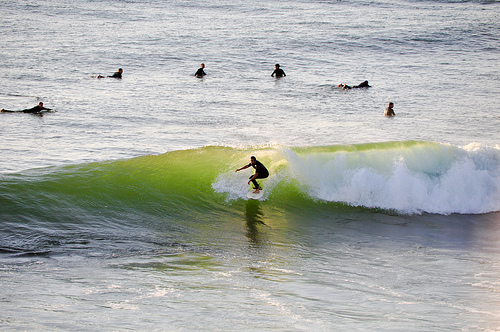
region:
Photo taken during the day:
[6, 10, 486, 323]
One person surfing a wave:
[220, 145, 275, 212]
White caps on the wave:
[240, 146, 490, 217]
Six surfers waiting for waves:
[0, 55, 400, 120]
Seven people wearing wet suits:
[12, 35, 412, 212]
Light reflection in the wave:
[142, 155, 343, 210]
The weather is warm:
[5, 3, 495, 321]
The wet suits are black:
[16, 45, 426, 221]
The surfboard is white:
[230, 186, 272, 208]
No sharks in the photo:
[6, 8, 488, 321]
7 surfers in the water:
[7, 45, 440, 217]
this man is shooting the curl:
[225, 139, 301, 211]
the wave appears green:
[131, 167, 203, 185]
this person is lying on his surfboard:
[6, 99, 64, 121]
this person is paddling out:
[338, 72, 373, 96]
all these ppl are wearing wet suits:
[1, 60, 377, 200]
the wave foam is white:
[346, 161, 472, 209]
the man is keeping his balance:
[236, 148, 273, 206]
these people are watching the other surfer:
[7, 56, 231, 123]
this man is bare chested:
[385, 93, 397, 126]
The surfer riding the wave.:
[233, 147, 269, 202]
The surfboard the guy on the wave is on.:
[245, 176, 265, 198]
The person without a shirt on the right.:
[380, 99, 397, 123]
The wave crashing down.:
[87, 145, 493, 227]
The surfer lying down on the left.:
[14, 93, 66, 133]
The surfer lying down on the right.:
[331, 68, 368, 94]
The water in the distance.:
[2, 0, 496, 58]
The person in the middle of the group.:
[189, 62, 209, 79]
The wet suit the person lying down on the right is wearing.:
[339, 80, 369, 90]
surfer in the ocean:
[191, 59, 216, 82]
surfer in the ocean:
[99, 65, 124, 86]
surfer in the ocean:
[13, 98, 57, 117]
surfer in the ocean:
[268, 61, 290, 90]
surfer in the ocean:
[334, 80, 374, 97]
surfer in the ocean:
[371, 95, 401, 125]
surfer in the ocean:
[225, 147, 269, 201]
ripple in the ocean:
[206, 121, 236, 138]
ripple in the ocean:
[306, 123, 323, 137]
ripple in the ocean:
[383, 279, 410, 294]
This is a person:
[86, 60, 129, 92]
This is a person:
[0, 93, 57, 130]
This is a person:
[234, 146, 286, 208]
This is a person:
[184, 55, 221, 93]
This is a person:
[264, 51, 290, 86]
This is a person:
[331, 70, 373, 94]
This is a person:
[377, 95, 398, 125]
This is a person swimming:
[86, 63, 137, 88]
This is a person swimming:
[189, 56, 209, 83]